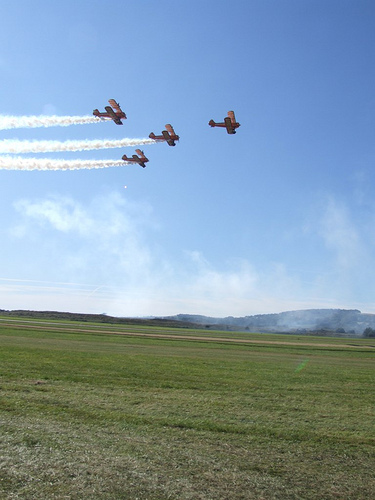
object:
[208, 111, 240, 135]
plane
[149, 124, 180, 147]
plane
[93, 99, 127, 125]
plane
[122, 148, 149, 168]
plane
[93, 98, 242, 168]
planes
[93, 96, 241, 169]
formation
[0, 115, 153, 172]
smoke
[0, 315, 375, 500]
ground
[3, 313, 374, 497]
field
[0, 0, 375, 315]
sky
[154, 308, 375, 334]
hill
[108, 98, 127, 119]
wing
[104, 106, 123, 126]
wing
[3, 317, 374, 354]
dirt